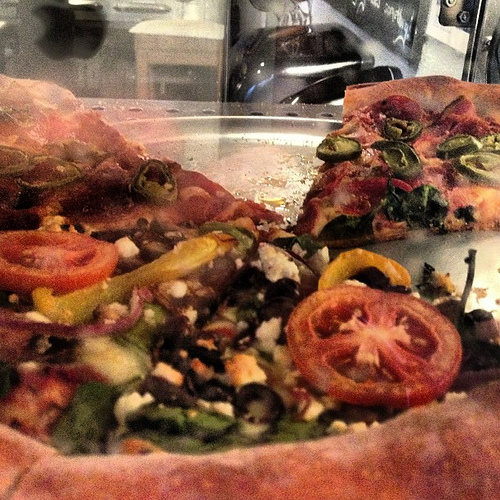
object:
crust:
[343, 71, 499, 126]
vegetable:
[234, 380, 283, 425]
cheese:
[258, 242, 301, 283]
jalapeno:
[131, 158, 178, 202]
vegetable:
[315, 246, 412, 291]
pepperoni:
[378, 95, 423, 121]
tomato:
[0, 227, 120, 303]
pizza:
[0, 71, 498, 500]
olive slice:
[264, 276, 304, 304]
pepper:
[30, 233, 221, 326]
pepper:
[13, 153, 81, 191]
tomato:
[287, 282, 462, 405]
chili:
[315, 135, 364, 162]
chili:
[381, 116, 423, 142]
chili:
[436, 132, 483, 159]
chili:
[457, 148, 499, 188]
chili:
[2, 145, 32, 177]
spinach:
[382, 180, 450, 224]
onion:
[0, 288, 144, 338]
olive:
[146, 374, 193, 408]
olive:
[255, 297, 297, 326]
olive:
[184, 365, 235, 401]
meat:
[328, 175, 384, 211]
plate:
[77, 96, 500, 332]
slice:
[0, 75, 291, 228]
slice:
[0, 218, 275, 497]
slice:
[3, 230, 499, 499]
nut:
[456, 10, 471, 24]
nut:
[444, 0, 456, 8]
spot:
[164, 108, 180, 114]